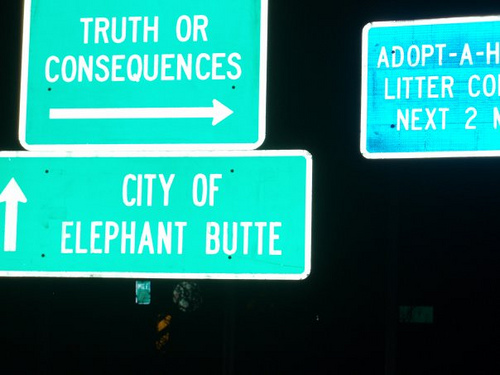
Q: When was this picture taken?
A: At night.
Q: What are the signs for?
A: Directions.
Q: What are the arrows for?
A: Directions.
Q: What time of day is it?
A: Late at night.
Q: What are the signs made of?
A: Metal.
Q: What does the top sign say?
A: Truth or Consequences.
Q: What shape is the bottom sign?
A: Rectangle.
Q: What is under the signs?
A: Road.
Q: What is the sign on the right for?
A: Adopt a Highway.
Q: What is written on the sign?
A: Truth or consequences.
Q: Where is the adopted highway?
A: Next 2 miles.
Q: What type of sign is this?
A: Directional.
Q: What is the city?
A: Elephant Butte.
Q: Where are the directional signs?
A: On the road.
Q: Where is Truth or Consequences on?
A: A sign.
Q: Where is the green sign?
A: On the road.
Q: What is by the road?
A: Traffic signs.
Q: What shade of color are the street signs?
A: Green.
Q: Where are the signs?
A: On the posts.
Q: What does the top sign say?
A: Truth or consequences.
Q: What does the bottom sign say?
A: City of elephant butte.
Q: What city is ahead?
A: Elephant butte.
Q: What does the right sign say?
A: Adopt a highway litter control next 2 miles.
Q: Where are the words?
A: On the signs.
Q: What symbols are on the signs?
A: Arrows.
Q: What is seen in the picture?
A: Boards.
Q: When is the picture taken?
A: Night time.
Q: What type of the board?
A: Direction board.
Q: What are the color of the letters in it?
A: White.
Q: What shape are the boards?
A: Square and rectangle.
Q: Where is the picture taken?
A: On a street.